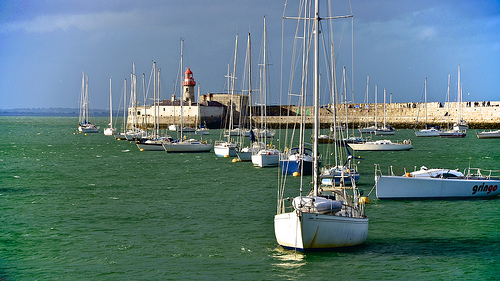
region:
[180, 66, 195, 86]
the top of the lighthouse is red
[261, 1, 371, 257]
the sailboat is in the water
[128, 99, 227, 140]
stone building at the end of the pier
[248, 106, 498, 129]
stone bridge/walkway behind the building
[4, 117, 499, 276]
the water color is green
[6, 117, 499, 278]
the water is calm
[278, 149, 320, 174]
this sailboat is blue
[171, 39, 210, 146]
the masks are made of metal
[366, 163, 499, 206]
this is a motor boat not a sail boat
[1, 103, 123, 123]
the mountains are off in the distance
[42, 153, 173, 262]
The water is green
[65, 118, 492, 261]
Boats on the water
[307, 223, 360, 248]
Rust on the ships hull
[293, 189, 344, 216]
A raft on the boat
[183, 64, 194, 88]
a red lighthouse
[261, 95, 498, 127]
a wall on the water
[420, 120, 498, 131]
Water damage on the wall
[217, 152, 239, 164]
yellow water bouys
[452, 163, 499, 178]
rail on the boat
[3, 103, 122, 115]
Forrested hills on the land in the distance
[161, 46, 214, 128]
A lighthouse in the distance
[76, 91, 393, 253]
Boats in the water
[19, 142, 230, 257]
The water is still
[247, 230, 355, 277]
The boat's reflection underneath the boat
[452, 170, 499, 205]
"Gringe" on the side of the boat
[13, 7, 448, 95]
The sky is sunny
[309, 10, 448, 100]
Clouds are in the sky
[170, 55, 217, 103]
Red and white are the color of the lighthouse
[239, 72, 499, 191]
This is a port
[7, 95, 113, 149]
Mountains in the background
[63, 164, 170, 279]
The water is blue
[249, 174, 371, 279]
The boat is docked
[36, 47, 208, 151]
The sails are tall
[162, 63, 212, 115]
A light house is in the back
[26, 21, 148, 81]
The sky is blue and clear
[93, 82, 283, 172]
A building is in the back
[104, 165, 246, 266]
The water is calm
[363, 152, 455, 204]
The boat is white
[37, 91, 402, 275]
Many boats are docked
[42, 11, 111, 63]
Few clouds are in the sky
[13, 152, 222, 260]
Water is green and clear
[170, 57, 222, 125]
Lighthouse in the background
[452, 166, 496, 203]
Boat says gringo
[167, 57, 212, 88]
The top of the lighthouse is red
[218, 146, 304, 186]
Boats tied down by yellow anchors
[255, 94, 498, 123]
Cement wall along the dock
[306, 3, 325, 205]
Metal pole down the center of the boat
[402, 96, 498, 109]
People standing on the boat dock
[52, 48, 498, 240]
The boats are all stationary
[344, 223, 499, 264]
The boat is casting a shadow in the water